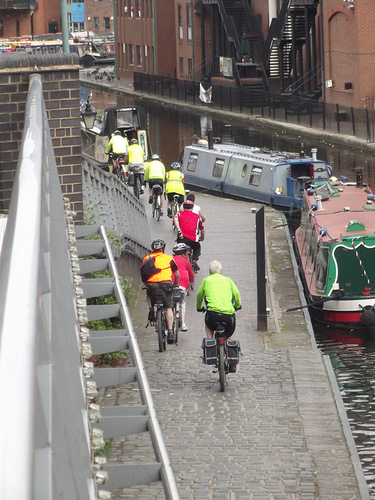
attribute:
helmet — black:
[169, 240, 192, 255]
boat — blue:
[180, 140, 330, 215]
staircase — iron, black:
[223, 6, 272, 106]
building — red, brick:
[321, 12, 374, 119]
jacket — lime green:
[200, 268, 238, 317]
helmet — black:
[148, 236, 167, 254]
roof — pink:
[327, 199, 357, 223]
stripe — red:
[315, 310, 363, 321]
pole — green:
[58, 4, 68, 54]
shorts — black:
[203, 309, 235, 338]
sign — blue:
[68, 3, 84, 24]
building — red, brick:
[113, 2, 373, 127]